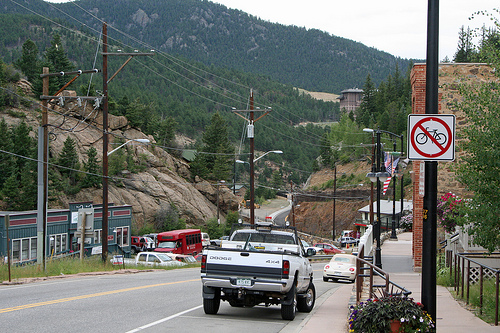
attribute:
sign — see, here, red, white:
[410, 118, 469, 176]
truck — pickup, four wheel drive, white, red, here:
[199, 217, 323, 303]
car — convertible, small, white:
[324, 253, 359, 283]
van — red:
[324, 231, 345, 258]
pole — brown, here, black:
[230, 85, 269, 240]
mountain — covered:
[178, 1, 352, 88]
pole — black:
[407, 0, 465, 326]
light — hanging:
[358, 118, 404, 145]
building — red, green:
[4, 190, 140, 267]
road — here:
[103, 265, 164, 301]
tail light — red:
[278, 256, 297, 277]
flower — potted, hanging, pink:
[367, 288, 390, 314]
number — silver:
[255, 253, 288, 270]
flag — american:
[378, 168, 407, 200]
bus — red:
[158, 227, 212, 256]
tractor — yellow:
[233, 197, 267, 214]